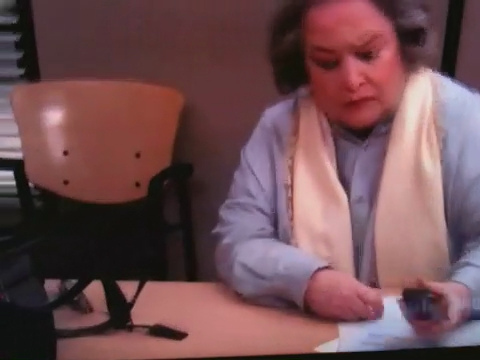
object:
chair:
[6, 78, 197, 281]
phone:
[396, 286, 448, 322]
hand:
[397, 277, 471, 339]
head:
[262, 0, 430, 130]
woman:
[210, 1, 480, 337]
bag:
[1, 247, 151, 360]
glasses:
[56, 279, 94, 313]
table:
[44, 279, 338, 360]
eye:
[315, 53, 339, 69]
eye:
[356, 49, 382, 61]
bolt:
[63, 149, 70, 156]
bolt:
[134, 153, 143, 159]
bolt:
[134, 181, 141, 189]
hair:
[372, 1, 428, 69]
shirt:
[211, 70, 480, 317]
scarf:
[286, 63, 450, 295]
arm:
[147, 162, 193, 186]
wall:
[32, 1, 281, 282]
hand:
[308, 266, 383, 325]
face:
[311, 33, 392, 128]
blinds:
[1, 12, 18, 28]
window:
[1, 1, 31, 189]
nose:
[343, 59, 365, 93]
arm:
[212, 115, 330, 315]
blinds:
[1, 51, 23, 63]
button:
[356, 197, 363, 203]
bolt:
[64, 179, 69, 185]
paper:
[316, 293, 480, 359]